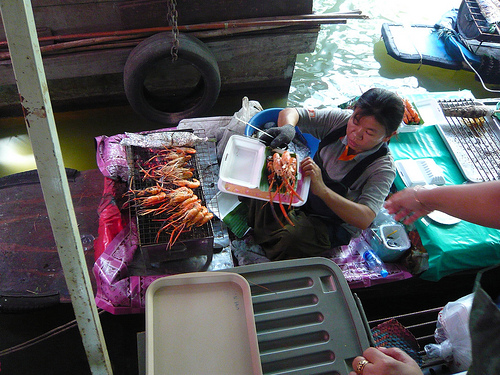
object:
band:
[357, 360, 370, 375]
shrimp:
[159, 143, 196, 155]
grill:
[125, 128, 227, 276]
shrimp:
[136, 161, 201, 188]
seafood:
[260, 150, 305, 234]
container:
[217, 134, 315, 207]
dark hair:
[353, 88, 406, 146]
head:
[346, 87, 406, 151]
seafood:
[120, 142, 214, 253]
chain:
[166, 5, 180, 64]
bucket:
[245, 107, 321, 161]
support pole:
[2, 0, 115, 375]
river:
[0, 0, 496, 176]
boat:
[1, 90, 500, 316]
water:
[318, 60, 356, 97]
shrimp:
[152, 202, 215, 251]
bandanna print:
[94, 260, 144, 314]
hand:
[346, 347, 424, 375]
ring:
[355, 358, 367, 372]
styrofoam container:
[218, 135, 302, 196]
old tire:
[123, 30, 219, 125]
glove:
[259, 124, 295, 149]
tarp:
[389, 117, 499, 283]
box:
[394, 158, 446, 188]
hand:
[258, 126, 295, 149]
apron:
[238, 123, 390, 261]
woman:
[237, 88, 404, 261]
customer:
[346, 160, 499, 375]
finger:
[352, 355, 370, 372]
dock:
[0, 0, 500, 375]